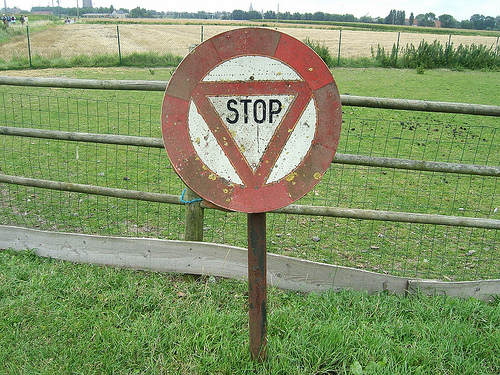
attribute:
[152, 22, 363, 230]
sign — metal, rusted, circle, stop, red, foreign, forefront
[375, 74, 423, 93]
grass — dry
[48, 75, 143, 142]
board — wooden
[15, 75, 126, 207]
fence — wooden, metal, uneven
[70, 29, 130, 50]
field — dry, fall, harvest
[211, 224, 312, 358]
pole — rusted, rusty, wooden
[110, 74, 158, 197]
boards — wooden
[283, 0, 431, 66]
trees — line, planted